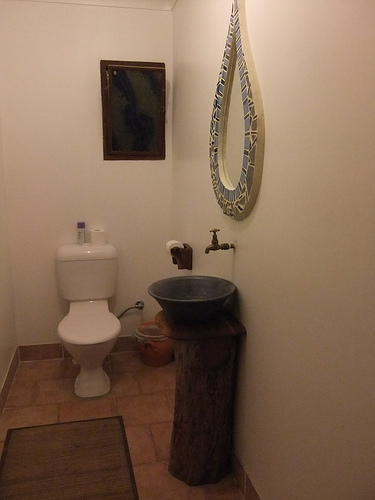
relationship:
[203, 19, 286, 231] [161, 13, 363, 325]
mirror on wall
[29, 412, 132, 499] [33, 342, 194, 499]
rug on floor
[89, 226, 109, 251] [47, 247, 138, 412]
tissue on toilet